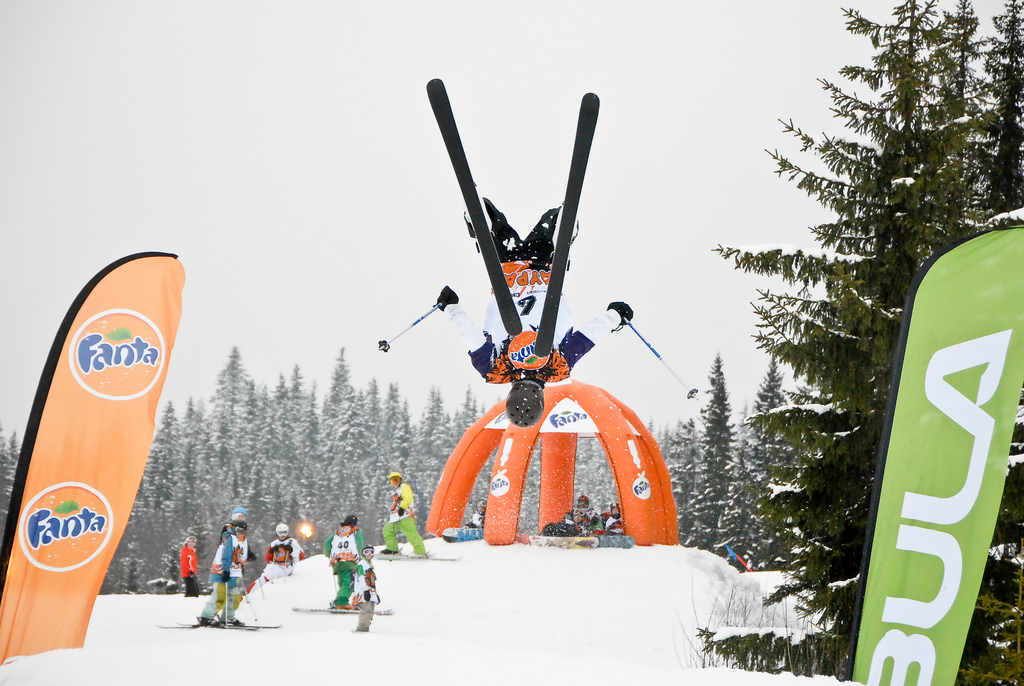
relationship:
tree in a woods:
[680, 348, 738, 552] [2, 1, 1020, 682]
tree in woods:
[648, 425, 674, 476] [2, 1, 1020, 682]